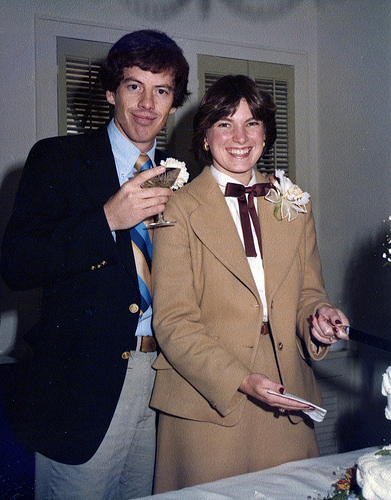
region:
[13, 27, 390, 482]
a man and woman cutting a wedding cake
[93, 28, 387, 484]
a bride and groom cutting a wedding cake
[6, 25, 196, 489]
a man dressed in a suit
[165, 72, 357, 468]
a woman dressed in a dress suit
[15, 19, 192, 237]
a man holding a glass of champagne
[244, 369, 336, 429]
a hand holding a napkin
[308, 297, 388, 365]
a woman's hand holding a knife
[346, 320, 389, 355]
the blade of a knife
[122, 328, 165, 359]
the belt of a man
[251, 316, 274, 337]
the belt of a woman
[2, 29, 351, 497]
Man and a woman posing for a photo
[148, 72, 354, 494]
Woman wearing a beige suit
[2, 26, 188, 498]
Man wearing a black blazer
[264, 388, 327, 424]
White napkin in a woman's hand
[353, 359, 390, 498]
Edge of a multi-level white cake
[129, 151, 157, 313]
Blue and brown striped tie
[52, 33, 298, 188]
Two paneled window shutters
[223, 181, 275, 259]
Burgundy bow tie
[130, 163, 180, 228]
Fancy drinking glass in a person's hand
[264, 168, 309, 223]
White decorative flower on a person's jacket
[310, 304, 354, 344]
fork in woman's hand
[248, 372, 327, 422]
napkin in woman's right hand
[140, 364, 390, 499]
barely visible cake on table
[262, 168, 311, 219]
woman is wearing a corsage with a white flower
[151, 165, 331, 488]
woman is wearing a light brown dress suit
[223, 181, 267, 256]
dark ribbon tied in a bow at woman's collar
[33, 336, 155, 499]
man has grey slacks on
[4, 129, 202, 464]
man is wearing a dark blue sports coat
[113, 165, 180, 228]
man is holding a glass in his right hand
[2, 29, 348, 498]
man is standing close behind woman to her right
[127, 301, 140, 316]
gold button on the jacket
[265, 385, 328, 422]
white napkin in the woman's hand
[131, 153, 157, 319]
gold and blue tie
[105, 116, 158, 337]
light blue dress shirt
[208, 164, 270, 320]
white dress shirt on the woman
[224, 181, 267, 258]
brown ribbon around the woman's neck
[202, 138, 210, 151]
earring on the woman's ear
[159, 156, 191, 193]
white flower on the man's jacket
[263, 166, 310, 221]
white flower on the woman's jacket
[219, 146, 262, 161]
wide grin on woman's face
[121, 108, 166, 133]
man with trout lips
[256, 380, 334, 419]
white handkerchief in woman's hand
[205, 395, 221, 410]
brown button on brown jacket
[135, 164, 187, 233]
champagne glass in man's hand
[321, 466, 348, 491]
variety of flowers on table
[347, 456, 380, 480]
edge of white wedding cake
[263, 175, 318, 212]
white bouquet on woman's lapel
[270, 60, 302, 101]
gray blinds at the window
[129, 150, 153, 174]
edge of gold and blue tie